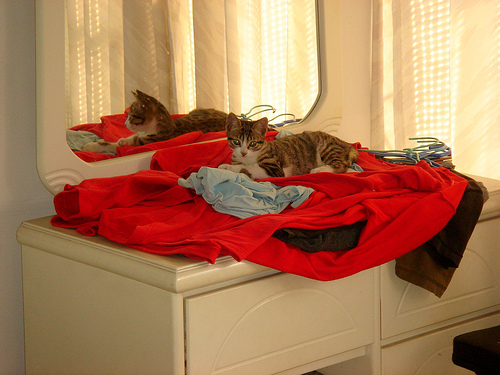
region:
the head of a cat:
[200, 95, 297, 183]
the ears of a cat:
[205, 100, 287, 133]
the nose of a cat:
[230, 143, 260, 158]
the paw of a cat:
[219, 154, 245, 176]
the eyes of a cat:
[220, 131, 278, 166]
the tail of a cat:
[316, 117, 396, 180]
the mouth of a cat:
[220, 142, 252, 176]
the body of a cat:
[200, 122, 351, 187]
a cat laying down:
[206, 91, 358, 208]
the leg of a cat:
[206, 126, 325, 193]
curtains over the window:
[402, 13, 455, 113]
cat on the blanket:
[238, 131, 360, 188]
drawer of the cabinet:
[208, 301, 343, 361]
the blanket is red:
[375, 186, 432, 225]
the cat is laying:
[214, 121, 364, 174]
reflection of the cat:
[122, 86, 228, 132]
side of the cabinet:
[34, 306, 102, 360]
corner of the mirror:
[40, 161, 82, 187]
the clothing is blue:
[215, 180, 274, 204]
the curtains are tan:
[465, 56, 478, 131]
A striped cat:
[218, 110, 359, 176]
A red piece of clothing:
[45, 125, 470, 280]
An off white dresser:
[15, 162, 495, 372]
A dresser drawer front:
[181, 250, 376, 370]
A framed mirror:
[32, 0, 347, 195]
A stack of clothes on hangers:
[51, 127, 491, 297]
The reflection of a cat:
[110, 90, 243, 147]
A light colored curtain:
[370, 2, 499, 177]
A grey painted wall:
[2, 1, 59, 373]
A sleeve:
[394, 177, 484, 297]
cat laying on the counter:
[221, 114, 379, 191]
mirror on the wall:
[28, 3, 368, 190]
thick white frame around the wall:
[15, 0, 370, 185]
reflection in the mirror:
[67, 2, 349, 171]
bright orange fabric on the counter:
[41, 128, 487, 297]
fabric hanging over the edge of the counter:
[231, 192, 485, 299]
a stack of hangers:
[366, 127, 467, 189]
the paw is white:
[215, 160, 242, 175]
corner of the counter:
[160, 260, 195, 298]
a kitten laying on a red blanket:
[225, 115, 357, 172]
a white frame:
[35, 0, 347, 192]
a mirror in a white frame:
[66, 0, 323, 160]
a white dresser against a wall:
[19, 161, 499, 373]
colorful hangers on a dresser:
[358, 137, 454, 170]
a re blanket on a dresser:
[51, 131, 466, 281]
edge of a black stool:
[451, 317, 498, 373]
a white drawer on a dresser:
[181, 265, 377, 372]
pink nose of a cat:
[240, 148, 249, 156]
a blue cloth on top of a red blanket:
[176, 163, 315, 216]